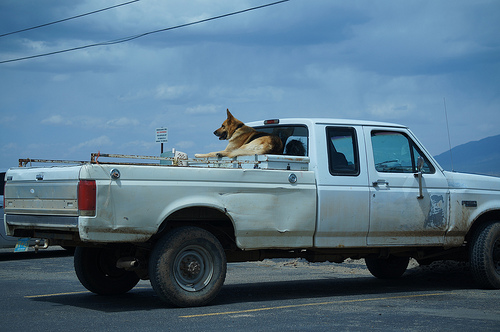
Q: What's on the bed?
A: Dog.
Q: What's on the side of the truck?
A: Dent.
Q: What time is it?
A: 5:34 PM.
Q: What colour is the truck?
A: White.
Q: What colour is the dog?
A: Brown.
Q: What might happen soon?
A: Rain.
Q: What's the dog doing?
A: Laying down.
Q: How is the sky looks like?
A: Cloudy.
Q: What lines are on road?
A: Yellow lines.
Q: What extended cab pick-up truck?
A: White.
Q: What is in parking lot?
A: White truck.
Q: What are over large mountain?
A: Cloudy skies.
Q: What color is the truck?
A: White.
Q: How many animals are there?
A: One.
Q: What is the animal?
A: Dog.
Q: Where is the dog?
A: Back of truck.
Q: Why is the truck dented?
A: It was wrecked.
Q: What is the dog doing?
A: Laying down.